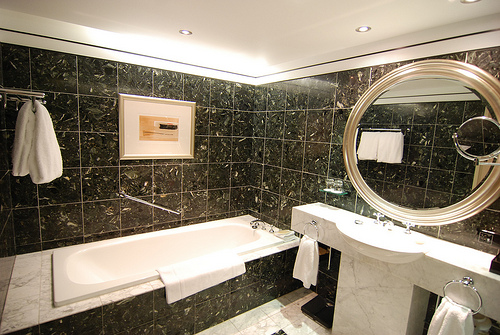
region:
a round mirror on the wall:
[346, 58, 499, 228]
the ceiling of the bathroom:
[3, 0, 498, 47]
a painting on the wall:
[114, 92, 194, 161]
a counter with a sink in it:
[294, 195, 498, 331]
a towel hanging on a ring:
[417, 274, 480, 334]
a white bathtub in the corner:
[47, 217, 287, 302]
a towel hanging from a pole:
[15, 95, 62, 183]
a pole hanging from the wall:
[115, 190, 185, 215]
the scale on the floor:
[301, 290, 333, 327]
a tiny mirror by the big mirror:
[458, 109, 497, 174]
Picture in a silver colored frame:
[108, 83, 230, 175]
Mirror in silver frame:
[329, 41, 481, 208]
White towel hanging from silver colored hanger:
[0, 82, 79, 209]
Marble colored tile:
[205, 92, 315, 198]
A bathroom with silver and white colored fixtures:
[9, 13, 486, 323]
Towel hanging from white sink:
[276, 210, 350, 304]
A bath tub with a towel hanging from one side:
[45, 205, 300, 302]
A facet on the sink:
[358, 198, 440, 245]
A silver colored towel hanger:
[433, 256, 495, 321]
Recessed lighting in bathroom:
[132, 10, 389, 67]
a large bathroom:
[2, 3, 497, 331]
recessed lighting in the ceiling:
[170, 22, 376, 40]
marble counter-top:
[286, 200, 494, 331]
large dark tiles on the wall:
[195, 81, 321, 196]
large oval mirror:
[341, 53, 497, 228]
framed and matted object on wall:
[107, 80, 207, 171]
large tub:
[28, 211, 303, 293]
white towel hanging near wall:
[2, 80, 107, 205]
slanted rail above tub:
[87, 180, 230, 263]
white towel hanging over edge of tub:
[138, 230, 255, 312]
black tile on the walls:
[206, 87, 309, 194]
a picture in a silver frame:
[110, 84, 207, 169]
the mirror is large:
[331, 63, 488, 250]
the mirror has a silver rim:
[340, 52, 497, 209]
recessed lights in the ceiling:
[170, 27, 377, 52]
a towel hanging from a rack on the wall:
[2, 84, 74, 191]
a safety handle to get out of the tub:
[110, 183, 190, 228]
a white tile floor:
[189, 280, 331, 333]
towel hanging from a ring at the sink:
[287, 205, 327, 292]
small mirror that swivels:
[445, 102, 497, 171]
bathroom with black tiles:
[68, 54, 425, 268]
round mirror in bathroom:
[337, 58, 489, 215]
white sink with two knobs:
[326, 198, 426, 262]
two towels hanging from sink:
[298, 213, 490, 333]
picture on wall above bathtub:
[104, 76, 204, 161]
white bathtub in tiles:
[26, 227, 295, 321]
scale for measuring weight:
[292, 287, 350, 330]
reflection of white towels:
[351, 119, 413, 165]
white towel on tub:
[141, 265, 253, 318]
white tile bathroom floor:
[227, 294, 332, 331]